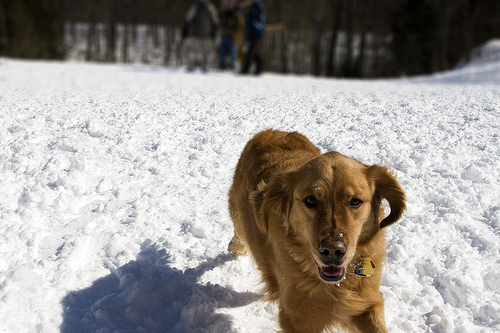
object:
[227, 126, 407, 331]
dog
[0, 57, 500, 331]
snow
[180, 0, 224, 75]
person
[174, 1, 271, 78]
group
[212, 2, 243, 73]
person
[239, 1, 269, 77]
person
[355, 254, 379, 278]
tag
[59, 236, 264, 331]
shadow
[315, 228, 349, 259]
nose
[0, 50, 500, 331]
ground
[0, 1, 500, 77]
tree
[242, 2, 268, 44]
jacket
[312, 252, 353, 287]
mouth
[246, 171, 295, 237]
ear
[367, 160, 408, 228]
ear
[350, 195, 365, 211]
left eye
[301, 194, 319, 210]
right eye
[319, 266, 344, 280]
tongue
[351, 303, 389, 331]
front leg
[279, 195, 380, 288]
neck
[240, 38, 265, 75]
pants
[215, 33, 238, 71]
pants